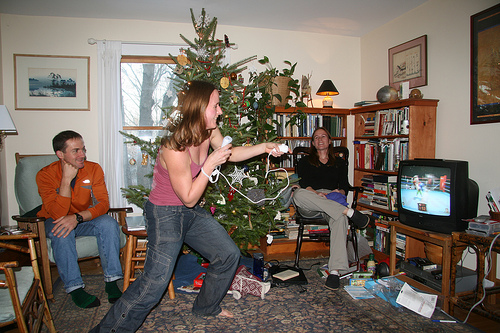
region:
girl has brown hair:
[171, 79, 223, 157]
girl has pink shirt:
[137, 145, 200, 216]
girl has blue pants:
[105, 184, 232, 331]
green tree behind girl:
[147, 5, 302, 251]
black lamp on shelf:
[313, 69, 353, 107]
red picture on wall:
[363, 39, 443, 114]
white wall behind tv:
[441, 115, 497, 187]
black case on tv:
[377, 160, 489, 215]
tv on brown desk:
[393, 216, 493, 326]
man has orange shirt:
[42, 164, 89, 228]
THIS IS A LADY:
[86, 76, 291, 331]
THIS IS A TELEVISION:
[394, 156, 481, 233]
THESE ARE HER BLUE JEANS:
[90, 205, 242, 332]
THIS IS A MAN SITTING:
[30, 130, 129, 320]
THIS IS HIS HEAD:
[50, 129, 90, 169]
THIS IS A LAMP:
[311, 77, 348, 109]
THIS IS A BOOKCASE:
[345, 95, 437, 264]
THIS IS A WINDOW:
[119, 60, 191, 218]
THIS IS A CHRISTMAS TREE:
[117, 5, 291, 262]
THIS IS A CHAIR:
[0, 237, 57, 331]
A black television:
[390, 148, 484, 232]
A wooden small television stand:
[382, 218, 484, 325]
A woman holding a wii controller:
[67, 82, 304, 314]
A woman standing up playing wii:
[67, 75, 304, 330]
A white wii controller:
[201, 132, 288, 211]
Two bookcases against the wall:
[255, 96, 427, 276]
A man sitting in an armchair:
[12, 117, 139, 297]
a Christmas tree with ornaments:
[124, 13, 294, 288]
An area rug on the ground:
[31, 261, 458, 331]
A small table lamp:
[314, 76, 341, 109]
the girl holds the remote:
[106, 69, 288, 329]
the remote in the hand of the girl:
[218, 132, 233, 169]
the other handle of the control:
[263, 138, 292, 163]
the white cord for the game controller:
[219, 158, 292, 208]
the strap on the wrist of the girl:
[200, 156, 221, 187]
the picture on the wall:
[9, 51, 91, 115]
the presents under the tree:
[232, 250, 277, 302]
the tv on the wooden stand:
[397, 161, 473, 226]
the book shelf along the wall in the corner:
[352, 104, 394, 213]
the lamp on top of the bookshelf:
[315, 78, 339, 108]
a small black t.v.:
[396, 155, 481, 232]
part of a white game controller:
[220, 133, 235, 146]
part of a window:
[118, 55, 188, 223]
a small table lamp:
[315, 80, 341, 107]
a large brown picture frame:
[11, 53, 91, 117]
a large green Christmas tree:
[117, 5, 293, 253]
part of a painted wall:
[257, 36, 353, 64]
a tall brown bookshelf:
[348, 101, 432, 263]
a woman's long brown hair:
[161, 78, 230, 146]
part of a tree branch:
[135, 60, 163, 123]